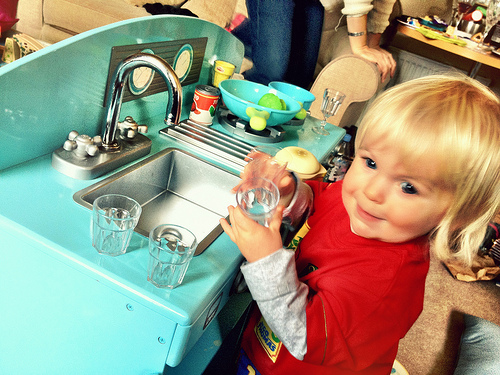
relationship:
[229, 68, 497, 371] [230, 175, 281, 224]
boy holding glass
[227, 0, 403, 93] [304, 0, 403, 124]
woman sitting on seat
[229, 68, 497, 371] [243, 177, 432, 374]
boy wearing tshirt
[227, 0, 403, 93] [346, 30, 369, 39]
woman wearing bracelet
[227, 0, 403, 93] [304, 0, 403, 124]
woman on seat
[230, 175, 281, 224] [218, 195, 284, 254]
glass in hand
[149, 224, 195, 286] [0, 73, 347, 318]
glass on surface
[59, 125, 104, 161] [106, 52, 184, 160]
knob on side of faucet